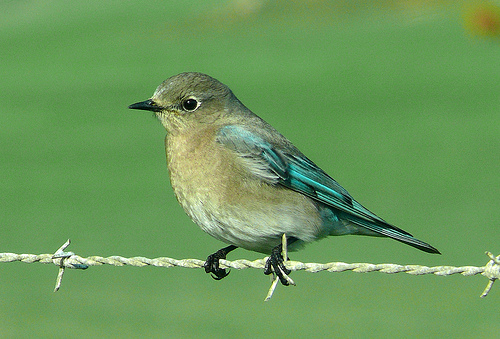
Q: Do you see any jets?
A: No, there are no jets.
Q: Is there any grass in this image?
A: Yes, there is grass.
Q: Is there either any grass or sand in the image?
A: Yes, there is grass.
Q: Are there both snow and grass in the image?
A: No, there is grass but no snow.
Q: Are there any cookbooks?
A: No, there are no cookbooks.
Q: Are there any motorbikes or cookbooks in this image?
A: No, there are no cookbooks or motorbikes.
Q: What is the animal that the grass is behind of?
A: The animal is a bird.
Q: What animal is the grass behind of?
A: The grass is behind the bird.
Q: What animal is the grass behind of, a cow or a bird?
A: The grass is behind a bird.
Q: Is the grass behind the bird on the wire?
A: Yes, the grass is behind the bird.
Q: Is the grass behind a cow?
A: No, the grass is behind the bird.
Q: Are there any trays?
A: No, there are no trays.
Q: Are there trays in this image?
A: No, there are no trays.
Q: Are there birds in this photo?
A: Yes, there is a bird.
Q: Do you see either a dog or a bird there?
A: Yes, there is a bird.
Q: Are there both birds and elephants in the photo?
A: No, there is a bird but no elephants.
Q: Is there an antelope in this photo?
A: No, there are no antelopes.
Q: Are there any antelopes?
A: No, there are no antelopes.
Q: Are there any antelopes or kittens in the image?
A: No, there are no antelopes or kittens.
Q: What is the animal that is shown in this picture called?
A: The animal is a bird.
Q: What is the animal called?
A: The animal is a bird.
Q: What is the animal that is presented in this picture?
A: The animal is a bird.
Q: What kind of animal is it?
A: The animal is a bird.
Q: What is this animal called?
A: This is a bird.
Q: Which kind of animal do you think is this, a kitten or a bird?
A: This is a bird.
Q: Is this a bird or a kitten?
A: This is a bird.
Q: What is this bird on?
A: The bird is on the wire.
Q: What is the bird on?
A: The bird is on the wire.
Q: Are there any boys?
A: No, there are no boys.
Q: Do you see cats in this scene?
A: No, there are no cats.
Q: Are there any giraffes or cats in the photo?
A: No, there are no cats or giraffes.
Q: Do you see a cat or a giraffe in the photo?
A: No, there are no cats or giraffes.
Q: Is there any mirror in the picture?
A: No, there are no mirrors.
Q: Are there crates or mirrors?
A: No, there are no mirrors or crates.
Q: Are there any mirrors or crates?
A: No, there are no mirrors or crates.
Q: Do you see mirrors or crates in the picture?
A: No, there are no mirrors or crates.